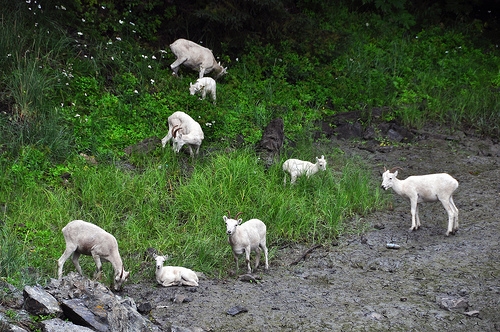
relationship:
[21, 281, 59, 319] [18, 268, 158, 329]
rock in a rock pile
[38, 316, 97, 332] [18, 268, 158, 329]
rock in a rock pile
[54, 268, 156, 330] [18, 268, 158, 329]
rock in a rock pile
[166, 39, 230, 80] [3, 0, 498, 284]
goat eating grass